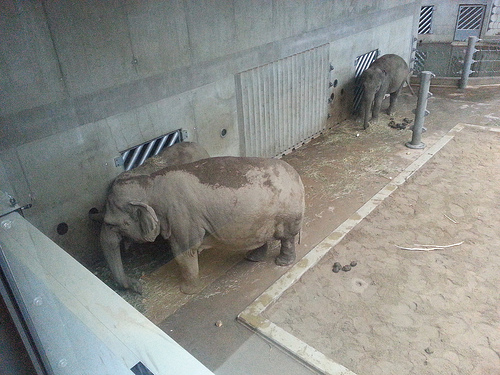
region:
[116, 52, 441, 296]
elephants in a concrete pen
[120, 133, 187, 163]
silver bar in a concrete wall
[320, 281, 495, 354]
sand in a concrete square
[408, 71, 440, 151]
a metal post in a pen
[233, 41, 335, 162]
a metal door in a wall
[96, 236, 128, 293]
a trunk on a elephant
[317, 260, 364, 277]
elephant poop on the ground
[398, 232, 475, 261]
a branch on the ground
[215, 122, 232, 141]
a hole in the concrete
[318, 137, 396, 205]
water on the concrete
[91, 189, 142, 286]
the trunk of a elephant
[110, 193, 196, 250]
the ear of a elephant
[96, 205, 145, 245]
the eye of a elephant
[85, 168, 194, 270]
the head of a elephant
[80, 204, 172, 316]
a big grey trunk of a elephant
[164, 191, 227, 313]
the legs of a elephant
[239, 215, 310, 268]
the back legs of a elephant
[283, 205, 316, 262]
the tail of a elephant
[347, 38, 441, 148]
a big grey elephant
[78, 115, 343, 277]
a elephant near a wall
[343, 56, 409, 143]
the trunk of a elephant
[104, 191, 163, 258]
the eye of a elephant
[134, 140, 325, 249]
the back of a elephant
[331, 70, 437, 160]
a elephant near a pole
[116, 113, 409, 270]
a big grey elephant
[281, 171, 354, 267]
the tail of a elephant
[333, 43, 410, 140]
the head of a elephant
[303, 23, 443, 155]
a elephant near a wall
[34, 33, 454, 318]
two elephants in a zoo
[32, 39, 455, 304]
the cage is cement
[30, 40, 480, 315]
there is poop on the floor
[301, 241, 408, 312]
elephant dung on ground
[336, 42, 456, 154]
elephant near elephant poop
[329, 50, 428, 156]
this elephant is grey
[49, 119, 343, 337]
this is an asian elephant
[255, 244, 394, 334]
the dirt is tan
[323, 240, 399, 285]
five nuggets of poop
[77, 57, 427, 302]
elephants in a cement pen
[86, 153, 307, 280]
an elephant against a wall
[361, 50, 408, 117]
an elephant standing up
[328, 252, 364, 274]
elephant poop on the ground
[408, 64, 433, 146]
a metal pole in the ground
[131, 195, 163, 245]
the ear of the elephant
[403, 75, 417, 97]
the tail of the elephant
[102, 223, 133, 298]
the trunk of the elephant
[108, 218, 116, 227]
the eye of the elephant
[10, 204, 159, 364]
a cement wall